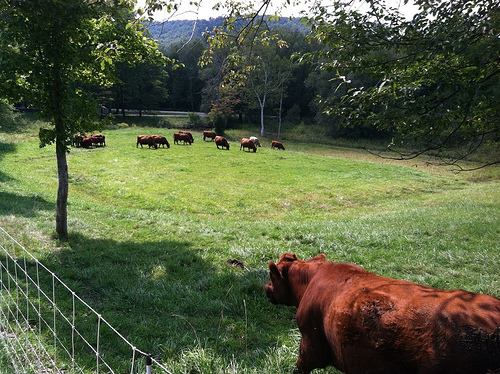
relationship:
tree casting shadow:
[3, 4, 190, 241] [11, 221, 306, 372]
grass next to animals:
[1, 107, 498, 369] [62, 124, 112, 154]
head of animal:
[261, 241, 322, 316] [264, 251, 497, 372]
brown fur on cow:
[272, 239, 435, 349] [262, 252, 498, 372]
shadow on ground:
[38, 229, 298, 361] [2, 114, 498, 372]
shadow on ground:
[0, 229, 297, 374] [2, 114, 498, 372]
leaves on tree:
[436, 92, 451, 105] [326, 43, 498, 155]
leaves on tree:
[387, 96, 401, 110] [326, 43, 498, 155]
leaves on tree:
[336, 92, 348, 104] [326, 43, 498, 155]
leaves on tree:
[469, 114, 478, 132] [326, 43, 498, 155]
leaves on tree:
[303, 103, 320, 110] [326, 43, 498, 155]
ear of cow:
[265, 257, 283, 284] [255, 243, 498, 371]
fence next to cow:
[1, 221, 183, 371] [255, 243, 498, 371]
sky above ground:
[195, 1, 216, 18] [103, 155, 383, 238]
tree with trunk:
[219, 33, 298, 135] [251, 72, 271, 132]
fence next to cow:
[0, 221, 176, 374] [262, 252, 498, 372]